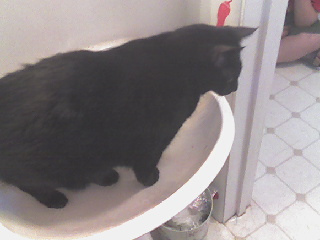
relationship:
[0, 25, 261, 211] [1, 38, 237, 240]
cat in sink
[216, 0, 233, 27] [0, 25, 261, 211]
pepper by cat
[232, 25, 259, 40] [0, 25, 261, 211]
ear on cat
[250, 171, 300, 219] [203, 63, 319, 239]
tile on floor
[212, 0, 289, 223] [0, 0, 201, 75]
jam on wall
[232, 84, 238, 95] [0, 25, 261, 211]
nose on cat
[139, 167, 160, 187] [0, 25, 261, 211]
paw on cat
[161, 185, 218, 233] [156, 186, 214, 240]
bag in bin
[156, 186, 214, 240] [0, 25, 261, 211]
bin under cat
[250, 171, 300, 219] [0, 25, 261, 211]
tile below cat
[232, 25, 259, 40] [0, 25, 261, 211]
ear of cat